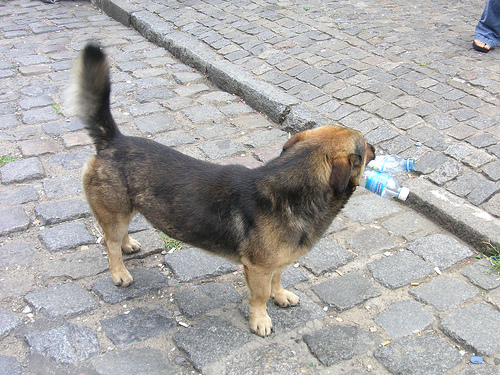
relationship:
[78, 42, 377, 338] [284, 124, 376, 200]
dog has head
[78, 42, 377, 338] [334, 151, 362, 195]
dog has ear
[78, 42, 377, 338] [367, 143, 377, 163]
dog has nose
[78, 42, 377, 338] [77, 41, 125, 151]
dog has tail